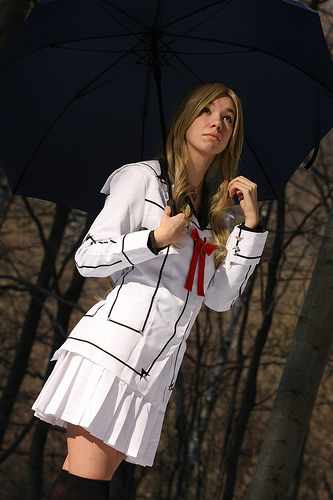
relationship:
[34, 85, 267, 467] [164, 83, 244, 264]
woman has hair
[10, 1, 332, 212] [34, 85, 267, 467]
umbrella above woman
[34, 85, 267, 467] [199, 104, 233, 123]
woman has eyes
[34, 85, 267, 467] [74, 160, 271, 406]
woman wearing jacket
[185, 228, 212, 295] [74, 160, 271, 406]
bow on front of jacket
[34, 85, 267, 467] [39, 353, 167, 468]
woman wearing skirt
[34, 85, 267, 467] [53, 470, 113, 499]
woman wearing stockings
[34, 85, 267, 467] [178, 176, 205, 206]
woman wearing necklace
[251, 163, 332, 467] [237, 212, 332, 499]
tree has trunk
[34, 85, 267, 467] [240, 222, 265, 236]
woman wearing shirt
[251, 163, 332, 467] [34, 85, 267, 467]
tree behind woman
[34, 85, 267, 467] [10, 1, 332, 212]
woman holding umbrella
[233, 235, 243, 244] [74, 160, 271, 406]
button on jacket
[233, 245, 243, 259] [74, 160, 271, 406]
button on jacket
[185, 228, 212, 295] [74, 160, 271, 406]
bow on jacket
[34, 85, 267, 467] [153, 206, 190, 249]
woman has hand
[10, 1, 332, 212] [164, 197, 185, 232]
umbrella has handle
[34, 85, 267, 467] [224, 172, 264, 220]
woman has hand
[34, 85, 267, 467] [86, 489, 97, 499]
woman has knee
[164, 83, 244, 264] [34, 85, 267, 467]
hair of woman